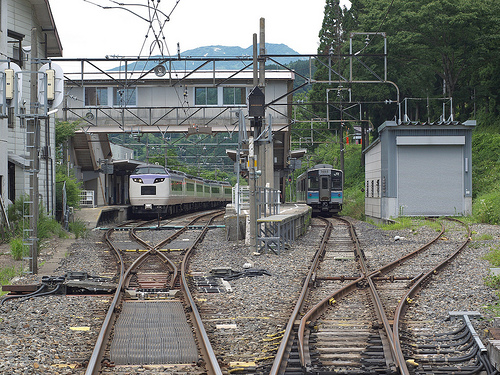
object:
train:
[129, 161, 235, 218]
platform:
[75, 204, 138, 226]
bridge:
[61, 105, 250, 135]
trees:
[305, 0, 367, 121]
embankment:
[299, 108, 499, 220]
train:
[293, 166, 345, 217]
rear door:
[320, 176, 331, 199]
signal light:
[155, 65, 165, 77]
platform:
[257, 200, 319, 253]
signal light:
[36, 61, 67, 111]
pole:
[29, 26, 43, 275]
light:
[154, 176, 165, 184]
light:
[131, 176, 142, 184]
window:
[84, 87, 109, 106]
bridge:
[61, 69, 294, 135]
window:
[113, 87, 136, 106]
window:
[196, 84, 219, 104]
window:
[223, 85, 246, 105]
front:
[128, 165, 170, 216]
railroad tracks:
[88, 209, 225, 374]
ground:
[0, 205, 500, 374]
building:
[0, 3, 64, 226]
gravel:
[185, 214, 324, 373]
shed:
[361, 118, 476, 219]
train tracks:
[270, 218, 472, 374]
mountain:
[113, 41, 312, 70]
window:
[13, 48, 25, 65]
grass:
[39, 216, 71, 241]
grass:
[11, 237, 25, 260]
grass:
[0, 263, 28, 286]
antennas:
[405, 66, 458, 125]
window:
[171, 179, 183, 191]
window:
[185, 180, 196, 191]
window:
[195, 180, 203, 192]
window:
[204, 185, 212, 193]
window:
[211, 186, 219, 195]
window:
[333, 178, 341, 189]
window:
[307, 177, 318, 190]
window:
[302, 179, 307, 192]